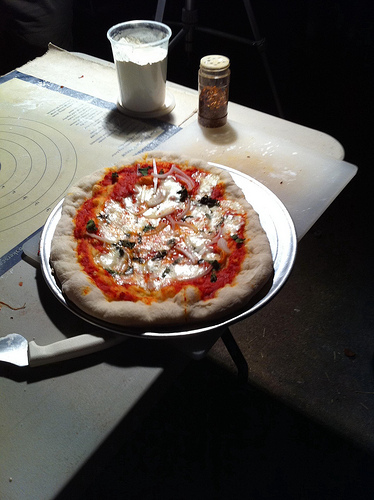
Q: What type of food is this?
A: Pizza.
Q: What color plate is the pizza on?
A: Silver.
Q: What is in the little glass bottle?
A: Pepper.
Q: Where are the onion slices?
A: On pizza.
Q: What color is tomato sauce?
A: Red.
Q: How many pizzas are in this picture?
A: 1.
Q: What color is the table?
A: White.